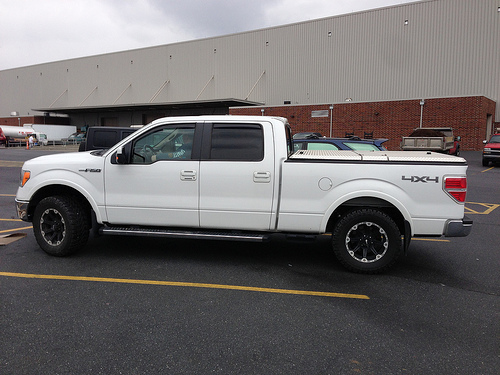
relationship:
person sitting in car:
[132, 125, 203, 169] [14, 115, 474, 269]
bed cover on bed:
[309, 151, 376, 156] [284, 136, 482, 248]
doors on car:
[198, 120, 275, 232] [14, 115, 474, 269]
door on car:
[103, 123, 200, 227] [14, 115, 474, 269]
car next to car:
[287, 138, 389, 152] [14, 115, 474, 269]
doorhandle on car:
[182, 160, 207, 197] [14, 115, 474, 269]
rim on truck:
[341, 219, 393, 263] [36, 89, 497, 288]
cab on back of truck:
[204, 113, 289, 232] [43, 142, 448, 290]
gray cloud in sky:
[280, 9, 309, 21] [2, 6, 344, 50]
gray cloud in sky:
[318, 2, 345, 18] [2, 6, 344, 50]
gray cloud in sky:
[125, 2, 149, 26] [2, 6, 344, 50]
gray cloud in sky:
[63, 7, 90, 38] [2, 6, 344, 50]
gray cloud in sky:
[8, 21, 44, 51] [2, 6, 344, 50]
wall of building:
[9, 0, 490, 151] [4, 7, 484, 154]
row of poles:
[39, 64, 290, 107] [36, 69, 283, 106]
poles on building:
[36, 69, 283, 106] [2, 0, 498, 162]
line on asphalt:
[6, 254, 383, 311] [20, 283, 475, 364]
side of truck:
[36, 147, 439, 253] [39, 61, 464, 283]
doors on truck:
[113, 120, 280, 225] [9, 67, 486, 279]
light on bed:
[442, 175, 466, 205] [289, 150, 467, 165]